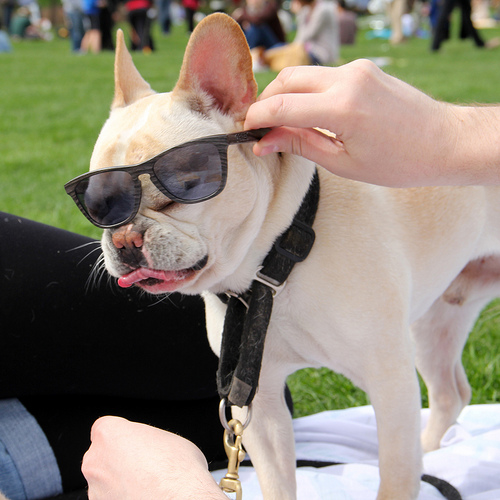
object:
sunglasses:
[64, 127, 274, 231]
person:
[0, 211, 293, 500]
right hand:
[242, 58, 499, 189]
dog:
[63, 12, 498, 500]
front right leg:
[203, 289, 296, 499]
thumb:
[252, 125, 351, 179]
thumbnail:
[259, 142, 281, 160]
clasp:
[219, 418, 246, 498]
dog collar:
[215, 164, 318, 409]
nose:
[111, 223, 144, 268]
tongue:
[117, 267, 182, 289]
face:
[83, 89, 273, 297]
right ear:
[110, 28, 157, 109]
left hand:
[81, 413, 224, 500]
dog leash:
[215, 165, 320, 499]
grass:
[0, 0, 500, 419]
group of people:
[0, 0, 484, 72]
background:
[0, 0, 499, 242]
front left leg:
[322, 226, 422, 499]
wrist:
[442, 102, 500, 187]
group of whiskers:
[64, 240, 117, 295]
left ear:
[170, 12, 260, 120]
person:
[95, 0, 114, 51]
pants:
[97, 5, 114, 51]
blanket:
[210, 402, 500, 498]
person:
[271, 0, 341, 66]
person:
[232, 0, 285, 51]